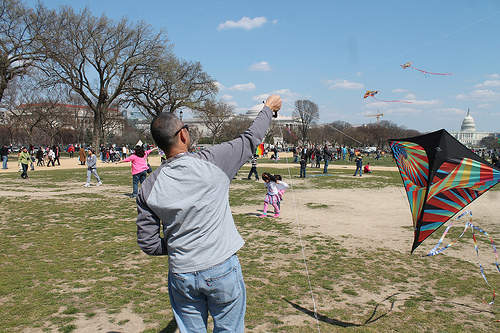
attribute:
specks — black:
[169, 122, 198, 140]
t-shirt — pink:
[120, 152, 154, 178]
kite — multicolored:
[385, 117, 499, 259]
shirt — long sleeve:
[125, 105, 281, 279]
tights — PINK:
[261, 202, 281, 216]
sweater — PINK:
[121, 149, 151, 176]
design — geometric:
[390, 138, 497, 248]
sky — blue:
[7, 1, 494, 139]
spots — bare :
[5, 168, 489, 331]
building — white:
[451, 109, 491, 148]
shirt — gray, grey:
[123, 144, 264, 277]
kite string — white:
[272, 114, 390, 332]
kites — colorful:
[359, 57, 451, 119]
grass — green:
[3, 165, 497, 330]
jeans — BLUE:
[156, 255, 253, 329]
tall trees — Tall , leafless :
[17, 3, 231, 174]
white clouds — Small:
[213, 13, 288, 36]